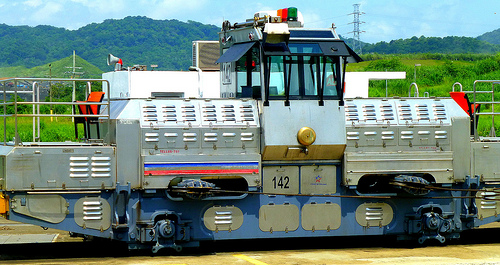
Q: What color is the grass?
A: Green.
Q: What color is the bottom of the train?
A: Blue.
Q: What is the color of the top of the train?
A: Silver.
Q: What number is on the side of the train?
A: 142.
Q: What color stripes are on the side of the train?
A: Red, White and Blue.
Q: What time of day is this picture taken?
A: In the daytime.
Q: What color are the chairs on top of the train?
A: Orange.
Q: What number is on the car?
A: 142.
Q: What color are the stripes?
A: Red and blue.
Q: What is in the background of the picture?
A: Powerlines.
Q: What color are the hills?
A: Green.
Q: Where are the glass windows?
A: On top.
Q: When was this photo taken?
A: Daytime.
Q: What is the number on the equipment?
A: 142.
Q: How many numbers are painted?
A: 3.